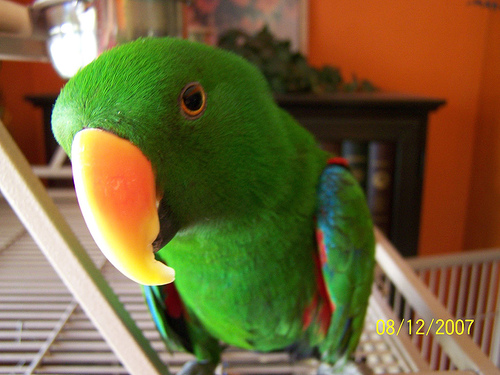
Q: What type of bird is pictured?
A: Parrot.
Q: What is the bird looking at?
A: The camera.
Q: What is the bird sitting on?
A: A cage.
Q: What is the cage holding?
A: A bird.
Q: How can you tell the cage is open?
A: You can see it's open.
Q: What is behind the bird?
A: A bookcase.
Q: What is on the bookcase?
A: A plant.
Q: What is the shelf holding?
A: Books.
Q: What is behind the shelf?
A: A wall.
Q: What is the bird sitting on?
A: A cage.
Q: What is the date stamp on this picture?
A: 08/12/2007.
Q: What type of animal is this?
A: Bird.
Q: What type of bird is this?
A: Parrot.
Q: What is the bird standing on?
A: Metal cage.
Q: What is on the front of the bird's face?
A: Beak.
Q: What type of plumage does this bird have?
A: Green.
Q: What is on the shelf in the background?
A: Books.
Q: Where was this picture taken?
A: Living room.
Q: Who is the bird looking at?
A: The person taking the picture.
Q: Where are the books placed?
A: Bookshelf.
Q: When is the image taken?
A: Parrot is standing.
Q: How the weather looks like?
A: Pleasant.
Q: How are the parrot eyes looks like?
A: Bright.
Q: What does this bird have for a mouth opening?
A: The bird has a beak.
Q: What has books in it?
A: The bookcase has books.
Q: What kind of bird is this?
A: This is a parrot.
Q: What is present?
A: A Bird.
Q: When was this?
A: Daytime.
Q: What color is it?
A: Green.